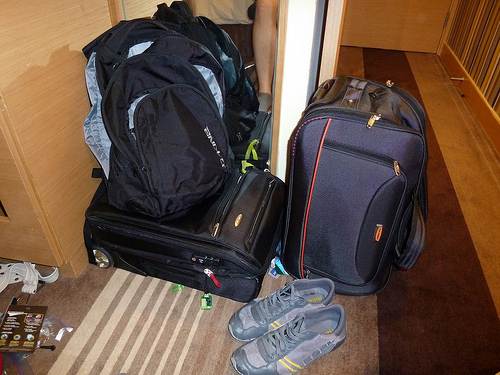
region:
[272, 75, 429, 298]
black piece of luggage with red details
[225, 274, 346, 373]
grey and yellow pair of tennis shoes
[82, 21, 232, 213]
blue and black bookbag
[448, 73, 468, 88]
metal door stop mounted on wall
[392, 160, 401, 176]
metal zipper pull on black item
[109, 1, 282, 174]
mirror reflecting luggage and a human figure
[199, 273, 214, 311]
green tag on a black piece of luggage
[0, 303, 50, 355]
brown piece of paper with white writing and graphics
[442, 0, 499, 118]
earth-toned vertically stripped wallpaper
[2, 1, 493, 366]
hotel room decorated in mostly brown colors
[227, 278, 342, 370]
pair of light blue sneakers with yellow stripes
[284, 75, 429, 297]
dark blue suitcase with a red stripe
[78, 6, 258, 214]
dark and light blue back pack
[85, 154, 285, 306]
dark blue suitcase with a red tag on the zipper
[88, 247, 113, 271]
silver and black wheel at the bottom of a suitcase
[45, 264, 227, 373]
tan and gray stripes in brown carpeting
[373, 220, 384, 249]
brand logo on dark blue suitcase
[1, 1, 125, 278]
wood grained closet of a hotel room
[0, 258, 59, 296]
white cloth article with straps on the floor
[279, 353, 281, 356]
part of a shoe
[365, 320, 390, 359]
edge of a mat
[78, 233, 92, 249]
part of a drawer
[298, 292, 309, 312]
part of a shoe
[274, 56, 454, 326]
this is a suitcase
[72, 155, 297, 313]
this is a black suitcase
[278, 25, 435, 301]
the suitcase is blue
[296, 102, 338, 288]
red stripe on suitcase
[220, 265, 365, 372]
a pair of tennis shoes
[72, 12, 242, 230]
this is a backpack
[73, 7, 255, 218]
the backpack is black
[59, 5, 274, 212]
the backpack is open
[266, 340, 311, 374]
yellow stripes on shoes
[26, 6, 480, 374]
luggage in a corner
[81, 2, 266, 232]
a dark blue backpack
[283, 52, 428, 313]
a black suit case with red stripe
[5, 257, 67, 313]
a white belt on the floor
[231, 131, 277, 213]
neon green string on backpack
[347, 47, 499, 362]
brown carpet in a hallway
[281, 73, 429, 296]
big blue and red bag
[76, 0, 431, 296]
luggage on the floor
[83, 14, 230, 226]
black and blue bagpack on top of bag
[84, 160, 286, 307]
small black bag on the floor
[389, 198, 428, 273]
black handle of blue bag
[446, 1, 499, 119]
striped multicolored wall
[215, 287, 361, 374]
a pair of shoes on the floor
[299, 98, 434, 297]
a blue suitcase with a red stripe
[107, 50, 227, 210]
a black back pack on a suitcase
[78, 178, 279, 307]
a black suitcase on the floor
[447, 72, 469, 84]
a metal door stop attached to the wall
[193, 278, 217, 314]
a green tag on a suitcase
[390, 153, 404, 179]
a gold zipper on a suitcase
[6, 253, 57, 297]
a white belt on the floor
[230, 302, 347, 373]
a grey athletic shoe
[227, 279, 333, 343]
a grey athletic shoe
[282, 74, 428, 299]
a black piece of luggage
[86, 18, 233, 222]
a black back pack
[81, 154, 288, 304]
a black piece of luggage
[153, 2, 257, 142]
a black back pack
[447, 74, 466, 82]
a metal door stopper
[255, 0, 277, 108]
a person's leg